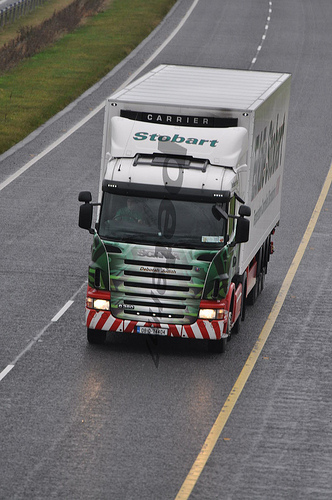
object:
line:
[170, 165, 330, 498]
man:
[110, 194, 144, 224]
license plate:
[140, 326, 169, 336]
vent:
[123, 257, 194, 321]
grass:
[49, 36, 89, 66]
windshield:
[97, 190, 227, 246]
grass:
[8, 64, 55, 108]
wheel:
[236, 272, 247, 322]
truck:
[78, 64, 292, 358]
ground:
[260, 53, 299, 70]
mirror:
[78, 191, 93, 230]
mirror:
[235, 205, 252, 244]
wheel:
[209, 297, 231, 353]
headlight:
[198, 306, 217, 320]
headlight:
[93, 299, 109, 310]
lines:
[1, 1, 272, 384]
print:
[132, 131, 218, 148]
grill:
[105, 255, 217, 325]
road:
[1, 0, 330, 499]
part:
[197, 306, 208, 320]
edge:
[218, 338, 227, 353]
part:
[205, 163, 224, 180]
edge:
[222, 373, 250, 427]